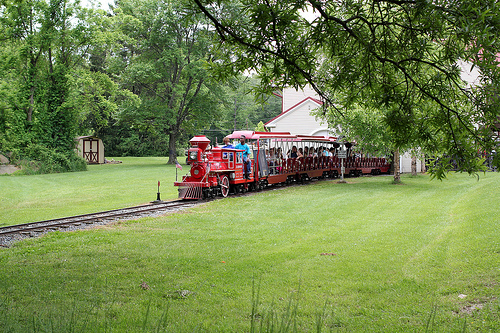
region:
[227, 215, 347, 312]
The grass is green.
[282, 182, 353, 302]
The grass is green.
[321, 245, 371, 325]
The grass is green.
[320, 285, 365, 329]
The grass is green.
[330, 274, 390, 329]
The grass is green.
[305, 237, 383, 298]
The grass is green.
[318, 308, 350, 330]
The grass is green.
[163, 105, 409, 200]
A little red train.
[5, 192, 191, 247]
The tracks in front of a train.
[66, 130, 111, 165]
A shed in the distance.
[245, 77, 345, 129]
A white building in the background.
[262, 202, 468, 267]
The grass is green.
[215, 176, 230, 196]
The wheel on a train.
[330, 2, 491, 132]
Green leaves on a tree.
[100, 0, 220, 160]
A tree in the distance.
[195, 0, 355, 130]
The branch on a tree.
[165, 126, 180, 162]
The trunk of a tree.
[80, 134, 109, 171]
Barn house in the bushes.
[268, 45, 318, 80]
Branches sprouting out from trees.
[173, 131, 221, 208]
The front of the choo choo train.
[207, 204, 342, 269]
Freshly cut lawn.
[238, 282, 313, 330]
Green weeds growing in front.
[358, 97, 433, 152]
The leaves on the branches.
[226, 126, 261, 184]
The conductor of the Choo Choo train.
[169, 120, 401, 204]
The Choo Choo train.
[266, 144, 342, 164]
People riding the Choo Choo train.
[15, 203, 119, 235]
The train tracks.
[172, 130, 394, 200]
a red train filled with people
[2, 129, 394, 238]
train on train tracks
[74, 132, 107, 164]
a brown and white shed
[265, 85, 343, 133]
red and white building behind train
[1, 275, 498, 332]
tall green grass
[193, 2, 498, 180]
tree branches over lawn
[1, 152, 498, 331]
a nice green lawn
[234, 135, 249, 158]
man in blue shirt driving train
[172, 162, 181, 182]
a small flag pole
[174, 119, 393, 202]
a red engine pulling open passenger cars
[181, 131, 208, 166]
the smoke stack on the engine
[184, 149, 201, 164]
the train has a head light on the engine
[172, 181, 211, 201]
the engine has a cowcatcher on the front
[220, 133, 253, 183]
the engineers riding in the engine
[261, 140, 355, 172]
passengers riding in the train cars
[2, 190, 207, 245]
the train runs on a narrow guage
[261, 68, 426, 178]
the train is moving out of a building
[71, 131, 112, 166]
a shed is in the yard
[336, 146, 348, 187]
a sign is on a pole